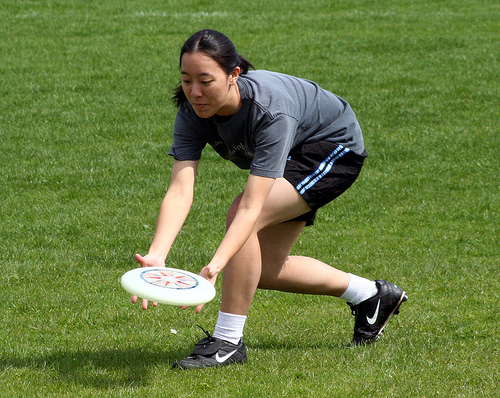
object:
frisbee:
[118, 265, 216, 308]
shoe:
[345, 278, 408, 347]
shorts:
[270, 134, 367, 227]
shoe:
[173, 332, 249, 370]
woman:
[128, 29, 412, 376]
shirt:
[163, 70, 366, 181]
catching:
[119, 241, 221, 316]